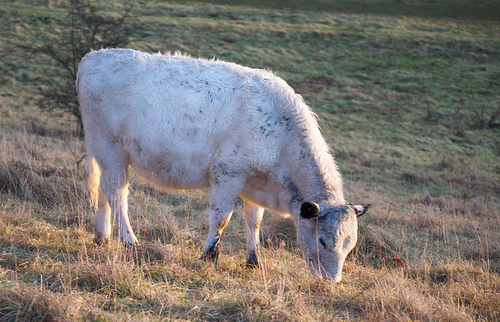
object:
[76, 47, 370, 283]
cow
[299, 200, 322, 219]
ear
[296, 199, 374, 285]
head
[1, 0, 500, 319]
grass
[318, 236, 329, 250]
eye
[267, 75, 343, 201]
mane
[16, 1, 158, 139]
tree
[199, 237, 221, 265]
marking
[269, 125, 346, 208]
neck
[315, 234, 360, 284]
face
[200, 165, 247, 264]
leg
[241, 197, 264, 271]
leg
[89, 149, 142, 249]
leg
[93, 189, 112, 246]
leg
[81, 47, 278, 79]
back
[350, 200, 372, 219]
ears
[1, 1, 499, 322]
picture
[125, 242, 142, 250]
hoof